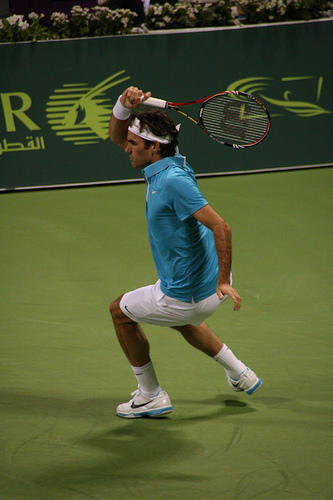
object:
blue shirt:
[140, 152, 218, 304]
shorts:
[118, 270, 233, 329]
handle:
[138, 94, 166, 108]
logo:
[125, 306, 134, 316]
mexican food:
[114, 382, 174, 422]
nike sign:
[227, 363, 262, 395]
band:
[112, 95, 132, 122]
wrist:
[109, 95, 129, 124]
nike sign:
[135, 372, 141, 375]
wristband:
[109, 92, 129, 121]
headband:
[128, 117, 182, 144]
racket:
[139, 90, 270, 150]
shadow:
[39, 392, 253, 488]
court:
[0, 160, 333, 500]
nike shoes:
[115, 387, 172, 421]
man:
[105, 104, 264, 419]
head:
[125, 107, 179, 168]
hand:
[120, 85, 151, 110]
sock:
[130, 359, 162, 394]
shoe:
[226, 366, 262, 396]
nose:
[125, 142, 132, 153]